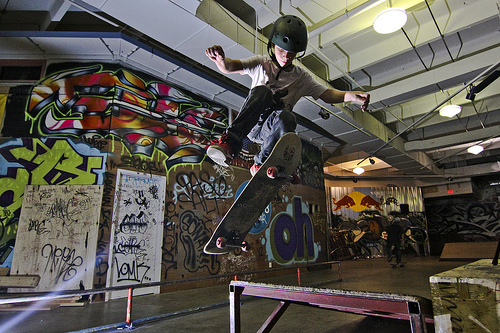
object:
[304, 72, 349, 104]
arm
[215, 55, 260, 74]
arm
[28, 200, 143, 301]
graffiti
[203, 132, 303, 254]
skate board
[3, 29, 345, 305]
wall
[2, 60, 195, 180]
collored graffiti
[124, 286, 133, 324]
rail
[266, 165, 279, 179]
wheel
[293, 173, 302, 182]
wheel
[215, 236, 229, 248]
wheel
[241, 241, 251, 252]
wheel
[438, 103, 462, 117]
light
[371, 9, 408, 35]
light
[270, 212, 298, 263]
word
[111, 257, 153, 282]
graffiti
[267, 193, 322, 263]
graffiti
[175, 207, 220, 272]
graffiti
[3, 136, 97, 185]
graffiti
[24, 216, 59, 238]
graffiti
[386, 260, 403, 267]
skateboard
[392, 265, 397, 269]
wheels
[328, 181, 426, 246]
wall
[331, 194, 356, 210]
logo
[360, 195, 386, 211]
logo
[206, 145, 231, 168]
shoe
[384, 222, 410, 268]
man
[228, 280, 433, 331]
ramp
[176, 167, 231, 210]
graffiti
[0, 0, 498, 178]
ceiling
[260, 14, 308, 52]
helmet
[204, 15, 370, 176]
boy